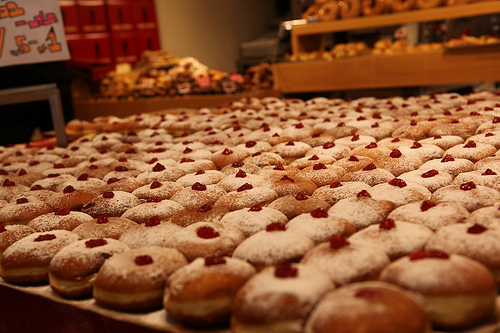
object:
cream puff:
[94, 245, 186, 310]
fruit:
[130, 255, 153, 267]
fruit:
[81, 237, 106, 249]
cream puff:
[47, 232, 123, 300]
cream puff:
[2, 227, 72, 284]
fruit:
[34, 231, 56, 244]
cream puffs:
[439, 140, 500, 160]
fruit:
[388, 138, 404, 143]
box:
[59, 1, 153, 70]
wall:
[63, 0, 263, 71]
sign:
[0, 3, 76, 70]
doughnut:
[230, 260, 335, 333]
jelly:
[199, 253, 225, 268]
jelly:
[270, 264, 300, 280]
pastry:
[232, 262, 334, 333]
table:
[123, 309, 153, 325]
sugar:
[315, 259, 355, 273]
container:
[135, 34, 162, 61]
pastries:
[380, 252, 496, 325]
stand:
[268, 42, 500, 95]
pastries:
[329, 42, 368, 60]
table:
[0, 82, 71, 149]